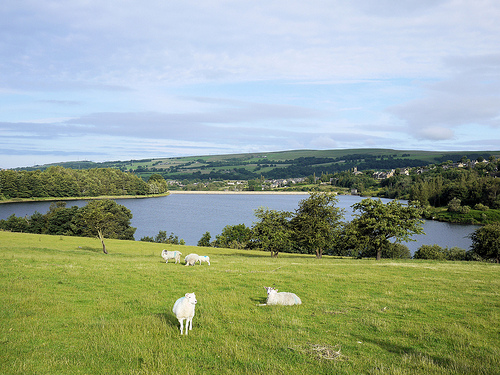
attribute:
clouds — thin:
[165, 33, 477, 121]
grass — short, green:
[3, 230, 499, 373]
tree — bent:
[73, 197, 120, 255]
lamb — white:
[171, 291, 196, 333]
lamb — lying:
[259, 284, 304, 306]